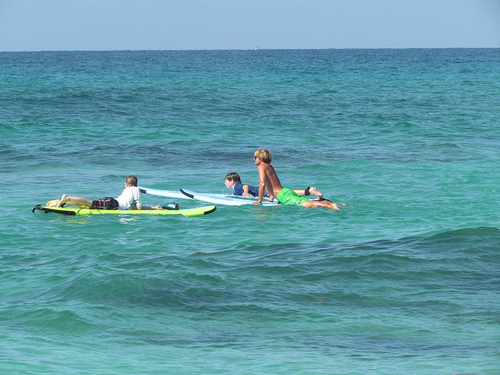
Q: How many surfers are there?
A: Three.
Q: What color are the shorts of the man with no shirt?
A: Green.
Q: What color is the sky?
A: Blue.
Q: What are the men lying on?
A: Surfboards.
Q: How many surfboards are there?
A: Three.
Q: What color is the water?
A: Blue.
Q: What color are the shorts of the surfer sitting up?
A: Green.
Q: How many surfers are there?
A: 3.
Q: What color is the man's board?
A: Blue.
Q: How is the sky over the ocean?
A: Blue.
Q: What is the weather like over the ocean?
A: Clear.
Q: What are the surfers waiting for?
A: Waves.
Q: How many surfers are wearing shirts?
A: 2.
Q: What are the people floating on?
A: Surfboards.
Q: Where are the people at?
A: In the ocean/water.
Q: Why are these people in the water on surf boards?
A: They are getting ready to surf.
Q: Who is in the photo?
A: Three people.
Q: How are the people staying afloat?
A: On surfboards.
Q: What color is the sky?
A: Blue.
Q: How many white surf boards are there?
A: Two.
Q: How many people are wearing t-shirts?
A: Two.